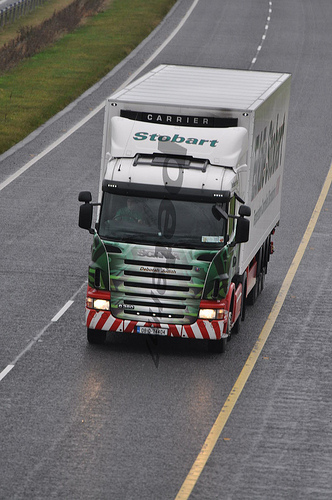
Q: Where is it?
A: This is at the road.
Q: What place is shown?
A: It is a road.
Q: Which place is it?
A: It is a road.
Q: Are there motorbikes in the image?
A: No, there are no motorbikes.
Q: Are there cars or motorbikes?
A: No, there are no motorbikes or cars.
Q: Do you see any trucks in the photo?
A: Yes, there is a truck.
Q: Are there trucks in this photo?
A: Yes, there is a truck.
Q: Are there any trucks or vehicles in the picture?
A: Yes, there is a truck.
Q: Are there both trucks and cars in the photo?
A: No, there is a truck but no cars.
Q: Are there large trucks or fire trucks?
A: Yes, there is a large truck.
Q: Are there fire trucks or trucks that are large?
A: Yes, the truck is large.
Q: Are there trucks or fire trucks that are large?
A: Yes, the truck is large.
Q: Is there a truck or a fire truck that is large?
A: Yes, the truck is large.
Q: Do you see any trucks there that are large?
A: Yes, there is a large truck.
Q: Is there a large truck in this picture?
A: Yes, there is a large truck.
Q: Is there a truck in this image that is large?
A: Yes, there is a truck that is large.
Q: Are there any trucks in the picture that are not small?
A: Yes, there is a large truck.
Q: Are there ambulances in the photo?
A: No, there are no ambulances.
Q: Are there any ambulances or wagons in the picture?
A: No, there are no ambulances or wagons.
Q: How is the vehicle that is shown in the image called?
A: The vehicle is a truck.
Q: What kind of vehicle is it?
A: The vehicle is a truck.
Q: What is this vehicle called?
A: This is a truck.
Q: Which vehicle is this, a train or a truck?
A: This is a truck.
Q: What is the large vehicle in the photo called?
A: The vehicle is a truck.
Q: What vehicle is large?
A: The vehicle is a truck.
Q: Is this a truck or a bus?
A: This is a truck.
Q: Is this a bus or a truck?
A: This is a truck.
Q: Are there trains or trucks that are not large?
A: No, there is a truck but it is large.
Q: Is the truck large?
A: Yes, the truck is large.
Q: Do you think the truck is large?
A: Yes, the truck is large.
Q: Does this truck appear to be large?
A: Yes, the truck is large.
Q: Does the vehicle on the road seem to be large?
A: Yes, the truck is large.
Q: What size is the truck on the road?
A: The truck is large.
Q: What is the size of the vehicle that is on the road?
A: The truck is large.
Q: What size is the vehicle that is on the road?
A: The truck is large.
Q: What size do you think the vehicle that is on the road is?
A: The truck is large.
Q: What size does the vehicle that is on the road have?
A: The truck has large size.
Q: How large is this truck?
A: The truck is large.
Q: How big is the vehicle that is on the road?
A: The truck is large.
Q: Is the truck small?
A: No, the truck is large.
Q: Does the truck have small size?
A: No, the truck is large.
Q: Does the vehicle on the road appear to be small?
A: No, the truck is large.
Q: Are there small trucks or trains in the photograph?
A: No, there is a truck but it is large.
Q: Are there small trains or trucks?
A: No, there is a truck but it is large.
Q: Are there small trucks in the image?
A: No, there is a truck but it is large.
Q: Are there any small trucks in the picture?
A: No, there is a truck but it is large.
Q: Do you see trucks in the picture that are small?
A: No, there is a truck but it is large.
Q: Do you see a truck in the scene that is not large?
A: No, there is a truck but it is large.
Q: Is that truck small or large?
A: The truck is large.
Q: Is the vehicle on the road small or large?
A: The truck is large.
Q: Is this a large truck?
A: Yes, this is a large truck.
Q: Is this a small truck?
A: No, this is a large truck.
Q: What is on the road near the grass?
A: The truck is on the road.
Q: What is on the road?
A: The truck is on the road.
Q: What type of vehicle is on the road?
A: The vehicle is a truck.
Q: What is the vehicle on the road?
A: The vehicle is a truck.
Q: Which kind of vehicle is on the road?
A: The vehicle is a truck.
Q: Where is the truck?
A: The truck is on the road.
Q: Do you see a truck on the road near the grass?
A: Yes, there is a truck on the road.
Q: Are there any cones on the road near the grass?
A: No, there is a truck on the road.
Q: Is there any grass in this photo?
A: Yes, there is grass.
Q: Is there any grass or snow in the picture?
A: Yes, there is grass.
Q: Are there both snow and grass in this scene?
A: No, there is grass but no snow.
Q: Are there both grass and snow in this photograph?
A: No, there is grass but no snow.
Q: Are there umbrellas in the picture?
A: No, there are no umbrellas.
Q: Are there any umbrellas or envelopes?
A: No, there are no umbrellas or envelopes.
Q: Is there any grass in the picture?
A: Yes, there is grass.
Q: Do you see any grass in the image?
A: Yes, there is grass.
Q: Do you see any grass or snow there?
A: Yes, there is grass.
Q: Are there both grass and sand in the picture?
A: No, there is grass but no sand.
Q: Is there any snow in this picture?
A: No, there is no snow.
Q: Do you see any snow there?
A: No, there is no snow.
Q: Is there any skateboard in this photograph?
A: No, there are no skateboards.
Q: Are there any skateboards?
A: No, there are no skateboards.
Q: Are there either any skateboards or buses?
A: No, there are no skateboards or buses.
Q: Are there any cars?
A: No, there are no cars.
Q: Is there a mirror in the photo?
A: Yes, there is a mirror.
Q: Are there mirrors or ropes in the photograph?
A: Yes, there is a mirror.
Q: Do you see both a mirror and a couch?
A: No, there is a mirror but no couches.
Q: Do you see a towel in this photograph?
A: No, there are no towels.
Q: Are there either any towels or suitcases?
A: No, there are no towels or suitcases.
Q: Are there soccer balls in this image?
A: No, there are no soccer balls.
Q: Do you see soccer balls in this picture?
A: No, there are no soccer balls.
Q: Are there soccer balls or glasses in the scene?
A: No, there are no soccer balls or glasses.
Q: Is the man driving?
A: Yes, the man is driving.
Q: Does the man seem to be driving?
A: Yes, the man is driving.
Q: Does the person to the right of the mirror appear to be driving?
A: Yes, the man is driving.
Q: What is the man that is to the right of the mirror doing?
A: The man is driving.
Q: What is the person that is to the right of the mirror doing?
A: The man is driving.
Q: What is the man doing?
A: The man is driving.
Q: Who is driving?
A: The man is driving.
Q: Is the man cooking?
A: No, the man is driving.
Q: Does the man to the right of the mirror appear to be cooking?
A: No, the man is driving.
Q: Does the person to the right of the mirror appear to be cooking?
A: No, the man is driving.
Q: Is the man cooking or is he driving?
A: The man is driving.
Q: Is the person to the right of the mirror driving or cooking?
A: The man is driving.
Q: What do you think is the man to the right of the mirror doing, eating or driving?
A: The man is driving.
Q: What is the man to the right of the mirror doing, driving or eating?
A: The man is driving.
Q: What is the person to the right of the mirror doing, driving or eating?
A: The man is driving.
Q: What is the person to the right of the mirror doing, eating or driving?
A: The man is driving.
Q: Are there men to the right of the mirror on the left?
A: Yes, there is a man to the right of the mirror.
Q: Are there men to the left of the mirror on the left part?
A: No, the man is to the right of the mirror.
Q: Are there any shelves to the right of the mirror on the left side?
A: No, there is a man to the right of the mirror.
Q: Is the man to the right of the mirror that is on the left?
A: Yes, the man is to the right of the mirror.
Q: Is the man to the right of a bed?
A: No, the man is to the right of the mirror.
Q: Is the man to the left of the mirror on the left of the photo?
A: No, the man is to the right of the mirror.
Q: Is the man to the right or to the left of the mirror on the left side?
A: The man is to the right of the mirror.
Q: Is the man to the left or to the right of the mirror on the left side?
A: The man is to the right of the mirror.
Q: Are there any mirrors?
A: Yes, there is a mirror.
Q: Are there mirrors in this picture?
A: Yes, there is a mirror.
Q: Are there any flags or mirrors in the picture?
A: Yes, there is a mirror.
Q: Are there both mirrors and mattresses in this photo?
A: No, there is a mirror but no mattresses.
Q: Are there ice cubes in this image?
A: No, there are no ice cubes.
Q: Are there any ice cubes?
A: No, there are no ice cubes.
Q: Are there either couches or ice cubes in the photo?
A: No, there are no ice cubes or couches.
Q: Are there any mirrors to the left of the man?
A: Yes, there is a mirror to the left of the man.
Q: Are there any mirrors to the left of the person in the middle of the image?
A: Yes, there is a mirror to the left of the man.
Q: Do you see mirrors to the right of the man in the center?
A: No, the mirror is to the left of the man.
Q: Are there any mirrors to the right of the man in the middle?
A: No, the mirror is to the left of the man.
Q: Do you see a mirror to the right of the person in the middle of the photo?
A: No, the mirror is to the left of the man.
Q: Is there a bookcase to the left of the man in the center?
A: No, there is a mirror to the left of the man.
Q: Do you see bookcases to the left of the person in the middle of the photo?
A: No, there is a mirror to the left of the man.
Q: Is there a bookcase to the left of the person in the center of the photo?
A: No, there is a mirror to the left of the man.